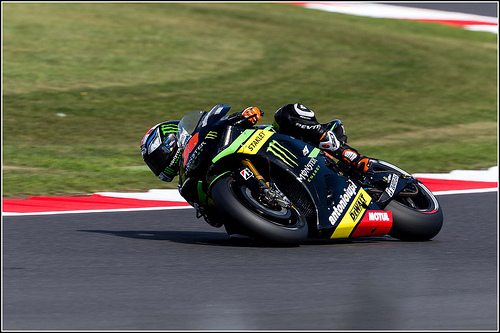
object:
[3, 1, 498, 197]
grass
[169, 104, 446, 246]
motorcycle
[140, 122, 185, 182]
helmet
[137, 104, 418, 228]
motorcyclist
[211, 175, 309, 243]
tire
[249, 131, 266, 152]
message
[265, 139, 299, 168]
logo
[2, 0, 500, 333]
track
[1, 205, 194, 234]
line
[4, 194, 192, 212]
red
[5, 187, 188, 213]
side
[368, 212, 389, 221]
motul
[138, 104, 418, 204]
man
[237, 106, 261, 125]
glove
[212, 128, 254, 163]
sticker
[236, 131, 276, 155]
sticker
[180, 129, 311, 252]
front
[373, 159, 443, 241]
wheel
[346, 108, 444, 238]
back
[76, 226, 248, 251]
shadow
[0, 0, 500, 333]
ground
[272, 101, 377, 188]
leg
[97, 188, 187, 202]
white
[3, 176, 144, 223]
boundary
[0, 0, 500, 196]
infield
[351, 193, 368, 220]
dewalt